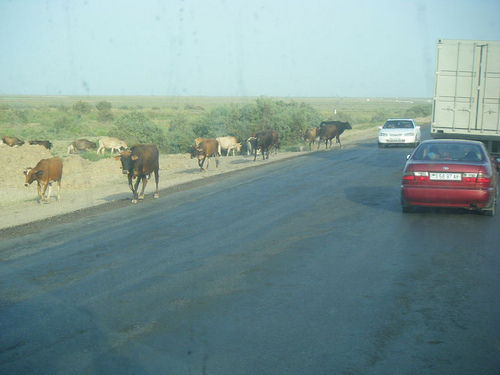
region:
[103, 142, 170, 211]
cow on side of road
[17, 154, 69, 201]
cow on side of road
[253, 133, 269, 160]
cow on side of road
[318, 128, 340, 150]
cow on side of road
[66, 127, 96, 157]
cow on side of road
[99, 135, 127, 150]
cow on side of road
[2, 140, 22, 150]
cow on side of road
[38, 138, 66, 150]
cow on side of road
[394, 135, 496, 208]
the car is red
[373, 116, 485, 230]
the car is red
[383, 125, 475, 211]
the car is red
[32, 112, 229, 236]
cows at the side of the road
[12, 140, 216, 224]
cows at the side of the road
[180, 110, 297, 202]
cows at the side of the road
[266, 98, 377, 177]
cows at the side of the road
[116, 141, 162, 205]
dark brown cow on the street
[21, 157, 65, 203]
light brown cow on the dirt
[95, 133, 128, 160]
white cow near the bushes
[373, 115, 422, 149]
white car on the street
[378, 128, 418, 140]
headlights on the white car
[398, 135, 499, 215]
red car behind the truck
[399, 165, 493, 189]
headlights on the red car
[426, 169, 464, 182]
white license plate on the red car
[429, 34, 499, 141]
truck in front of the red car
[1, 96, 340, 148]
green bushes near the cows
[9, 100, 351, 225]
a herd of cattle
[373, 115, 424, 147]
z white car on the road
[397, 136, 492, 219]
a red car on the road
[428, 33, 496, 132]
a semi on the road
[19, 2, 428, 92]
a clear blue sky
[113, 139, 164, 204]
a brown cow on the road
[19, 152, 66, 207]
a brown and white cow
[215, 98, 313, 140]
leafy green trees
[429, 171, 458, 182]
a number on a car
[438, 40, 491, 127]
doors on a trailer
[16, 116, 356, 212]
several cows loose on the side of a highway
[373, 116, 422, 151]
a white car on a highway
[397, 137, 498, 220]
a maroon car on the highway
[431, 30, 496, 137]
the back of a semi-truck trailer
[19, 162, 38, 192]
the head of a cow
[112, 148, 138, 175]
the head of a cow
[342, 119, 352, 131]
the head of a cow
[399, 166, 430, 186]
the tail light of a car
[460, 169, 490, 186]
the tail light of a car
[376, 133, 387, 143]
the headlight of a car